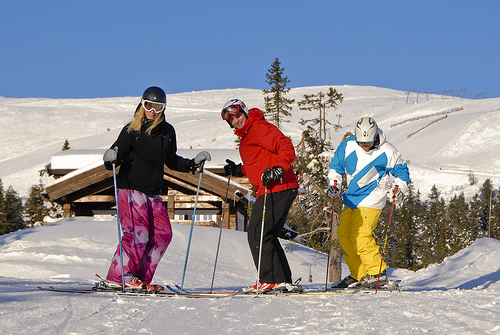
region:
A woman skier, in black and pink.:
[93, 85, 211, 297]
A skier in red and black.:
[219, 93, 308, 298]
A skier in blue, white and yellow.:
[328, 116, 419, 293]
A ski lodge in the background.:
[46, 141, 281, 234]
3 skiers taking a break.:
[89, 85, 412, 296]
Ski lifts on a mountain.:
[401, 85, 490, 112]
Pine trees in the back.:
[420, 178, 499, 268]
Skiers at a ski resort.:
[46, 74, 411, 300]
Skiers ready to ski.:
[93, 84, 412, 299]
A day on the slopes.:
[14, 54, 495, 315]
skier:
[100, 68, 184, 288]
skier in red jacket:
[218, 93, 300, 284]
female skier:
[327, 98, 419, 280]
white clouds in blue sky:
[431, 29, 479, 71]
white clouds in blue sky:
[355, 35, 399, 66]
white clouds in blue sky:
[402, 2, 459, 59]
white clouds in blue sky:
[310, 26, 382, 56]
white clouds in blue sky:
[187, 26, 214, 60]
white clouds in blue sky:
[87, 21, 112, 53]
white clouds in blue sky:
[17, 12, 79, 57]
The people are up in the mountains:
[36, 22, 462, 327]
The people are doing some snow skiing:
[47, 26, 458, 322]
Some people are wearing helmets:
[12, 30, 484, 321]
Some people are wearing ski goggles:
[35, 41, 480, 321]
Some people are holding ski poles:
[45, 26, 470, 316]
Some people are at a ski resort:
[31, 31, 451, 326]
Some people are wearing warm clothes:
[48, 30, 474, 323]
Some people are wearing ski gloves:
[53, 41, 444, 306]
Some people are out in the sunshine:
[48, 27, 443, 294]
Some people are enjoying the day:
[45, 27, 472, 319]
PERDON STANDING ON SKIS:
[217, 98, 309, 299]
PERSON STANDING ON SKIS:
[101, 80, 213, 299]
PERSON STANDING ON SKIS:
[320, 114, 412, 295]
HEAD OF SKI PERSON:
[351, 113, 383, 154]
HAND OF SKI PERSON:
[325, 173, 347, 196]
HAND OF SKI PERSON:
[383, 185, 407, 207]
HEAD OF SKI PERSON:
[213, 97, 254, 129]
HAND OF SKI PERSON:
[256, 161, 293, 195]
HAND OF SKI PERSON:
[216, 155, 241, 180]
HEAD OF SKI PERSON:
[136, 82, 170, 122]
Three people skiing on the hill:
[102, 86, 409, 294]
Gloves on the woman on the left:
[102, 145, 211, 171]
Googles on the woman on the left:
[140, 97, 164, 114]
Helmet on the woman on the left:
[140, 85, 166, 103]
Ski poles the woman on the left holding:
[110, 159, 203, 292]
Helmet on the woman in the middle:
[220, 98, 247, 126]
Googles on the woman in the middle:
[220, 104, 240, 121]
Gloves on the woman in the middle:
[222, 158, 284, 188]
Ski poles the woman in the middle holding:
[210, 167, 268, 294]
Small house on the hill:
[46, 143, 251, 230]